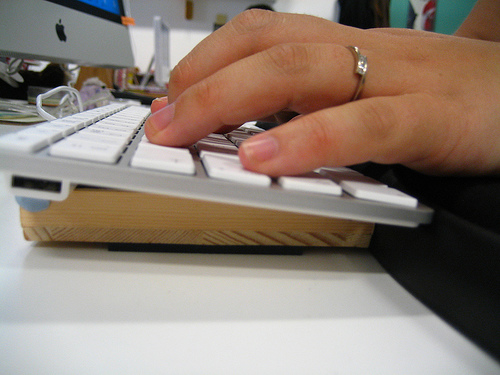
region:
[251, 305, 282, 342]
edge of a line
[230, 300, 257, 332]
part of a shade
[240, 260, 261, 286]
part of a shade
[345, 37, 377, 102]
person wearing a ring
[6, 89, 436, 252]
keyboard is white and gray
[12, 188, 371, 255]
keyboard stand underneath keyboard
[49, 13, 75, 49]
apple on the computer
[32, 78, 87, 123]
cord behind the keyboard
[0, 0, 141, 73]
the computer is gray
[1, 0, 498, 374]
picture zoomed in on person's hand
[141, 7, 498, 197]
person's fingers on keyboard keys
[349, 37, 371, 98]
diamond on the ring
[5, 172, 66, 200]
usb port on the keyboard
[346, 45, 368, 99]
silver ring on hand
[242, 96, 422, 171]
pinky of person typing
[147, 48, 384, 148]
finger of person typing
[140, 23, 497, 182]
hand on white keyboard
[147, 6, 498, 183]
hand of person typing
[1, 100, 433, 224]
white keyboard of mac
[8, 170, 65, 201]
usb port on keyboard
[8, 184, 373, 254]
wood base of keyboard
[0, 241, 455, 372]
white counter with keyboard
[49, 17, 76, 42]
the logo of apple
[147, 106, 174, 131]
a human finger nail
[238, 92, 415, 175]
finger of a human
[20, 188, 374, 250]
wood under the keyboard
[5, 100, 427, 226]
the keyboard is thin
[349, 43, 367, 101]
ring on the finger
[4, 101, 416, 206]
the keys are white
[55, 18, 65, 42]
a black apple logo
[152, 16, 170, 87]
monitor in the background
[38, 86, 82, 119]
the cable is white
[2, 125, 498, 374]
the desk is white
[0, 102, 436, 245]
keyboard on wood block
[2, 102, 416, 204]
white buttons on keyboard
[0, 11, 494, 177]
fingers on keyboard buttons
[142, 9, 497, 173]
ring on finger of hand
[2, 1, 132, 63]
bottom edge of monitor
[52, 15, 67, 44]
black logo on monitor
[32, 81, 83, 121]
white wire behind keyboard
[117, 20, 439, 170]
finger has silver ring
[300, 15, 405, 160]
finger has silver ring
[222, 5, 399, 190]
finger has silver ring